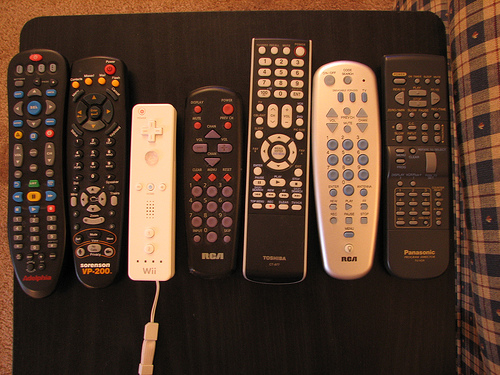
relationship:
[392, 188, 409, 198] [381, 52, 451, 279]
button on remote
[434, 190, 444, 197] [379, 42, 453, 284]
button on remote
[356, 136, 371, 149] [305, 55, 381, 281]
button on remote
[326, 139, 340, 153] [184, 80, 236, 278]
button on remote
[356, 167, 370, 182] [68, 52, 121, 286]
button on remote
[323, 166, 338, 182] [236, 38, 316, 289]
button on remote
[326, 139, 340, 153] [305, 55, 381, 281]
button on remote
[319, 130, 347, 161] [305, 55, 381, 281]
button on remote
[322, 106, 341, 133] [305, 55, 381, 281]
button on remote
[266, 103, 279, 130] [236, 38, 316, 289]
button on remote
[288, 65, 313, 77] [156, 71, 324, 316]
button on remote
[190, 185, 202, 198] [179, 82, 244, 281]
button on remote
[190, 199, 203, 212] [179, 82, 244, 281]
button on remote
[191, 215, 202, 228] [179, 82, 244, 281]
button on remote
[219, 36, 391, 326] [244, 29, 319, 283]
buttons are on controller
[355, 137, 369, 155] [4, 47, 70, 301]
button on controller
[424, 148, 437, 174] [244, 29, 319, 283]
button on controller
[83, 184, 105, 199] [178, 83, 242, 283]
button on controller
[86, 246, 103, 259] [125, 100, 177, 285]
button on controller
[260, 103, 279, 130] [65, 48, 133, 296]
button on controller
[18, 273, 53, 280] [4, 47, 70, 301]
lettering on controller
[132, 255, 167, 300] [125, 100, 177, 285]
lettering on controller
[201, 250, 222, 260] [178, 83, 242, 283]
lettering on controller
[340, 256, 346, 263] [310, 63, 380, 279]
black letter on controller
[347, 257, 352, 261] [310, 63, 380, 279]
black letter on controller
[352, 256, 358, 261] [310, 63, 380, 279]
black letter on controller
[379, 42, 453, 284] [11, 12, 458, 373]
remote on top of table top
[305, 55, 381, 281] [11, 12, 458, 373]
remote on top of table top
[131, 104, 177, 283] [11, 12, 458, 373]
remote on top of table top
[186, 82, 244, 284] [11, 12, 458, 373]
remote on top of table top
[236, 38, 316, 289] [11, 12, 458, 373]
remote on top of table top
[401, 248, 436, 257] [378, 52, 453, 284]
lettering on a controller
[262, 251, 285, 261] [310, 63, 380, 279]
lettering on a controller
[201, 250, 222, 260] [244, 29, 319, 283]
lettering on a controller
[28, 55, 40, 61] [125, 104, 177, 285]
lettering on a controller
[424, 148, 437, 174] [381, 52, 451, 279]
button on remote